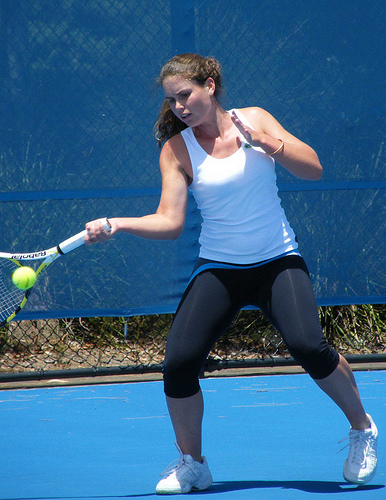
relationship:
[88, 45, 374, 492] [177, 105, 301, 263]
woman wears shirt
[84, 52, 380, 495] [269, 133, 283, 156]
woman wears bracelet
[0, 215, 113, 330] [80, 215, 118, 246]
racquet on hand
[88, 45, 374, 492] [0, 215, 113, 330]
woman has racquet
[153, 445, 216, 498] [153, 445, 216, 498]
foot on foot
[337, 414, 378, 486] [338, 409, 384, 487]
foot on foot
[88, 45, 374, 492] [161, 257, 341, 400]
woman has pants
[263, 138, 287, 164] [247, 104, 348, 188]
bracelet on woman's arm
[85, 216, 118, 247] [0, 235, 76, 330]
hand holding raquet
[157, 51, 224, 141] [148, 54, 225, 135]
hair on head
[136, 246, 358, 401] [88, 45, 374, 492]
pants on woman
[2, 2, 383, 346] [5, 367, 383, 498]
fence around court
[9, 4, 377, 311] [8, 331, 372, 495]
object on court